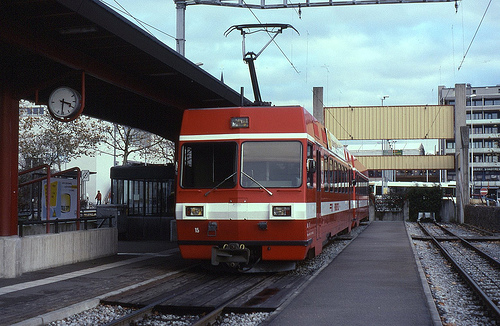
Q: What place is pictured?
A: It is a station.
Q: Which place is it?
A: It is a station.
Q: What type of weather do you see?
A: It is cloudy.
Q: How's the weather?
A: It is cloudy.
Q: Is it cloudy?
A: Yes, it is cloudy.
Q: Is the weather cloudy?
A: Yes, it is cloudy.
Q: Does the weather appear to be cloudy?
A: Yes, it is cloudy.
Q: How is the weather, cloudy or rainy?
A: It is cloudy.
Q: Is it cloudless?
A: No, it is cloudy.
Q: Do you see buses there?
A: No, there are no buses.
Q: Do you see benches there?
A: No, there are no benches.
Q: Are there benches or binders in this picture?
A: No, there are no benches or binders.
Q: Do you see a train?
A: Yes, there is a train.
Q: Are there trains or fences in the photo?
A: Yes, there is a train.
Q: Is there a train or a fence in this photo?
A: Yes, there is a train.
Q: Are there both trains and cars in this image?
A: Yes, there are both a train and a car.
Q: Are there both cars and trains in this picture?
A: Yes, there are both a train and a car.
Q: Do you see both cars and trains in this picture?
A: Yes, there are both a train and a car.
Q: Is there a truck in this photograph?
A: No, there are no trucks.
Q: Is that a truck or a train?
A: That is a train.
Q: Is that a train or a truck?
A: That is a train.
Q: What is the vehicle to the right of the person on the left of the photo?
A: The vehicle is a train.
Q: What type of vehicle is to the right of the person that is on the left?
A: The vehicle is a train.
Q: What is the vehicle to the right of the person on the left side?
A: The vehicle is a train.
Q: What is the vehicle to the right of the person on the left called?
A: The vehicle is a train.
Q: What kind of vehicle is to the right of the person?
A: The vehicle is a train.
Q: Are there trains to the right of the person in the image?
A: Yes, there is a train to the right of the person.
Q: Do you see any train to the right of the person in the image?
A: Yes, there is a train to the right of the person.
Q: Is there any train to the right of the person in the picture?
A: Yes, there is a train to the right of the person.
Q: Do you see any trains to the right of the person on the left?
A: Yes, there is a train to the right of the person.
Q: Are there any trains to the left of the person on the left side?
A: No, the train is to the right of the person.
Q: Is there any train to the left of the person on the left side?
A: No, the train is to the right of the person.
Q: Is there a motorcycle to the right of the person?
A: No, there is a train to the right of the person.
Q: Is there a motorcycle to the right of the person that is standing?
A: No, there is a train to the right of the person.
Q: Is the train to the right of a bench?
A: No, the train is to the right of a person.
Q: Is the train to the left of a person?
A: No, the train is to the right of a person.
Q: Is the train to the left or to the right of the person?
A: The train is to the right of the person.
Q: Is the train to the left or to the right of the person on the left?
A: The train is to the right of the person.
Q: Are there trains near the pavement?
A: Yes, there is a train near the pavement.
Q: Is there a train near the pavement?
A: Yes, there is a train near the pavement.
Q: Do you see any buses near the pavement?
A: No, there is a train near the pavement.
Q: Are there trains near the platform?
A: Yes, there is a train near the platform.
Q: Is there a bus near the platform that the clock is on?
A: No, there is a train near the platform.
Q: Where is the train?
A: The train is at the station.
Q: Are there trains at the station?
A: Yes, there is a train at the station.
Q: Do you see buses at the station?
A: No, there is a train at the station.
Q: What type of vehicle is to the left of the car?
A: The vehicle is a train.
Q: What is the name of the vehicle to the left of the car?
A: The vehicle is a train.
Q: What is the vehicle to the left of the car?
A: The vehicle is a train.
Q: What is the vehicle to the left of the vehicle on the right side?
A: The vehicle is a train.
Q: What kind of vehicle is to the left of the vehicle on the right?
A: The vehicle is a train.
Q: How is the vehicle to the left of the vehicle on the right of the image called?
A: The vehicle is a train.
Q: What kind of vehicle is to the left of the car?
A: The vehicle is a train.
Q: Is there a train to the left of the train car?
A: Yes, there is a train to the left of the car.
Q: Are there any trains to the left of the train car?
A: Yes, there is a train to the left of the car.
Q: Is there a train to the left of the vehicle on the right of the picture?
A: Yes, there is a train to the left of the car.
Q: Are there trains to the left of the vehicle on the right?
A: Yes, there is a train to the left of the car.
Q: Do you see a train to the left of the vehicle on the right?
A: Yes, there is a train to the left of the car.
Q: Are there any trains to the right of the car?
A: No, the train is to the left of the car.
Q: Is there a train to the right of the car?
A: No, the train is to the left of the car.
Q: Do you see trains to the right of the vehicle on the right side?
A: No, the train is to the left of the car.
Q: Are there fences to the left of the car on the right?
A: No, there is a train to the left of the car.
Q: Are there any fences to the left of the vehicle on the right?
A: No, there is a train to the left of the car.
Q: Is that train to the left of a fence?
A: No, the train is to the left of a car.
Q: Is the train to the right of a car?
A: No, the train is to the left of a car.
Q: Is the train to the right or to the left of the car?
A: The train is to the left of the car.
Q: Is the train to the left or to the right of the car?
A: The train is to the left of the car.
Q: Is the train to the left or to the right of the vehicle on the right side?
A: The train is to the left of the car.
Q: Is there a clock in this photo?
A: Yes, there is a clock.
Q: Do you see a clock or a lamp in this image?
A: Yes, there is a clock.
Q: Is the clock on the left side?
A: Yes, the clock is on the left of the image.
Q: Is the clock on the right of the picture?
A: No, the clock is on the left of the image.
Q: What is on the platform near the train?
A: The clock is on the platform.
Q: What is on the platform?
A: The clock is on the platform.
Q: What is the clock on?
A: The clock is on the platform.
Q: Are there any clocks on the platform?
A: Yes, there is a clock on the platform.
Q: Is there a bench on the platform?
A: No, there is a clock on the platform.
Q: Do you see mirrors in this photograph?
A: No, there are no mirrors.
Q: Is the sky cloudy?
A: Yes, the sky is cloudy.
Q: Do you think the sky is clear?
A: No, the sky is cloudy.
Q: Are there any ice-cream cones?
A: No, there are no ice-cream cones.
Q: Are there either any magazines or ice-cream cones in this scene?
A: No, there are no ice-cream cones or magazines.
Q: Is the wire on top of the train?
A: Yes, the wire is on top of the train.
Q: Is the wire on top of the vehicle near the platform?
A: Yes, the wire is on top of the train.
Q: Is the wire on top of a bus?
A: No, the wire is on top of the train.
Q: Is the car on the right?
A: Yes, the car is on the right of the image.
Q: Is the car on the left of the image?
A: No, the car is on the right of the image.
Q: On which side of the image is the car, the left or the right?
A: The car is on the right of the image.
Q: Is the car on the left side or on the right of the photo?
A: The car is on the right of the image.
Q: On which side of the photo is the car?
A: The car is on the right of the image.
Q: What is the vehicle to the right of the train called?
A: The vehicle is a car.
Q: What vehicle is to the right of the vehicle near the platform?
A: The vehicle is a car.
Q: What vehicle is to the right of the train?
A: The vehicle is a car.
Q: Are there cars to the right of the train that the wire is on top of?
A: Yes, there is a car to the right of the train.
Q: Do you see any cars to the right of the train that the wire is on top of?
A: Yes, there is a car to the right of the train.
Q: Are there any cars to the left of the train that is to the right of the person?
A: No, the car is to the right of the train.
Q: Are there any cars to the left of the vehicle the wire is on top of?
A: No, the car is to the right of the train.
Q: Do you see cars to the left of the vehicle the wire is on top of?
A: No, the car is to the right of the train.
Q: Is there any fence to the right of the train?
A: No, there is a car to the right of the train.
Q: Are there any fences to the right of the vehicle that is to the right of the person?
A: No, there is a car to the right of the train.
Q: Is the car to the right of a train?
A: Yes, the car is to the right of a train.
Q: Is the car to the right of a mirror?
A: No, the car is to the right of a train.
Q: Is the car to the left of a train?
A: No, the car is to the right of a train.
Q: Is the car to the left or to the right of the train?
A: The car is to the right of the train.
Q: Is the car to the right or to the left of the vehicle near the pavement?
A: The car is to the right of the train.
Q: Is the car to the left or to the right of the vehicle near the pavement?
A: The car is to the right of the train.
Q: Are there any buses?
A: No, there are no buses.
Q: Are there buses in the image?
A: No, there are no buses.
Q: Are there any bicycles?
A: No, there are no bicycles.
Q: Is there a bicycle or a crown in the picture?
A: No, there are no bicycles or crowns.